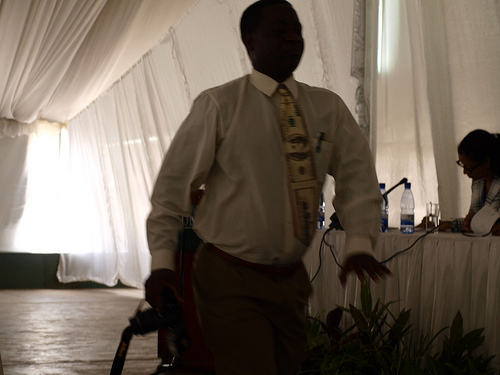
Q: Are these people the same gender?
A: No, they are both male and female.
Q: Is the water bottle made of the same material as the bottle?
A: Yes, both the water bottle and the bottle are made of plastic.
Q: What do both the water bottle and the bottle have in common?
A: The material, both the water bottle and the bottle are plastic.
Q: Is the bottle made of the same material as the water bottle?
A: Yes, both the bottle and the water bottle are made of plastic.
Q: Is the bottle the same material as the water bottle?
A: Yes, both the bottle and the water bottle are made of plastic.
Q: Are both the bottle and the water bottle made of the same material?
A: Yes, both the bottle and the water bottle are made of plastic.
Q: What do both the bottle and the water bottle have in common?
A: The material, both the bottle and the water bottle are plastic.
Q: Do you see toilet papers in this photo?
A: No, there are no toilet papers.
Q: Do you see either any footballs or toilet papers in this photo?
A: No, there are no toilet papers or footballs.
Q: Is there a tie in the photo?
A: Yes, there is a tie.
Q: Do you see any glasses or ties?
A: Yes, there is a tie.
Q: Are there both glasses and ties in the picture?
A: Yes, there are both a tie and glasses.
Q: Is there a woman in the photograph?
A: Yes, there is a woman.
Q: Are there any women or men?
A: Yes, there is a woman.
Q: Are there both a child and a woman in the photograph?
A: No, there is a woman but no children.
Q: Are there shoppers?
A: No, there are no shoppers.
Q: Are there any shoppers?
A: No, there are no shoppers.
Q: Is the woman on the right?
A: Yes, the woman is on the right of the image.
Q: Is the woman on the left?
A: No, the woman is on the right of the image.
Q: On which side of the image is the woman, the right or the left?
A: The woman is on the right of the image.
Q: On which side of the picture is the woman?
A: The woman is on the right of the image.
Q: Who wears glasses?
A: The woman wears glasses.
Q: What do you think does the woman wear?
A: The woman wears glasses.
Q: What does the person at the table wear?
A: The woman wears glasses.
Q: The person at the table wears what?
A: The woman wears glasses.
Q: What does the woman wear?
A: The woman wears glasses.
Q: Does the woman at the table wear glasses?
A: Yes, the woman wears glasses.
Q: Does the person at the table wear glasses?
A: Yes, the woman wears glasses.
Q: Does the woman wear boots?
A: No, the woman wears glasses.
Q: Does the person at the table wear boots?
A: No, the woman wears glasses.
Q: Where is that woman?
A: The woman is at the table.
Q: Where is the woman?
A: The woman is at the table.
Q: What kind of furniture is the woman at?
A: The woman is at the table.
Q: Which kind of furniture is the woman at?
A: The woman is at the table.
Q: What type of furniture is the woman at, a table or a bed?
A: The woman is at a table.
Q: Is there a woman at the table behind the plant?
A: Yes, there is a woman at the table.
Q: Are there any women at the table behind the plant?
A: Yes, there is a woman at the table.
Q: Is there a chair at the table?
A: No, there is a woman at the table.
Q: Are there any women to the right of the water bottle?
A: Yes, there is a woman to the right of the water bottle.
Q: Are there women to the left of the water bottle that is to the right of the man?
A: No, the woman is to the right of the water bottle.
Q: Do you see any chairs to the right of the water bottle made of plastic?
A: No, there is a woman to the right of the water bottle.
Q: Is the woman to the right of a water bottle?
A: Yes, the woman is to the right of a water bottle.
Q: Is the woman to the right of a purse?
A: No, the woman is to the right of a water bottle.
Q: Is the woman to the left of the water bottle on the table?
A: No, the woman is to the right of the water bottle.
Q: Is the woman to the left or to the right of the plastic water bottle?
A: The woman is to the right of the water bottle.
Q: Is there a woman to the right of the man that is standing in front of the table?
A: Yes, there is a woman to the right of the man.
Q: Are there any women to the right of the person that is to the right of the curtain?
A: Yes, there is a woman to the right of the man.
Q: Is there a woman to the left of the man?
A: No, the woman is to the right of the man.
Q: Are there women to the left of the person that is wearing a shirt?
A: No, the woman is to the right of the man.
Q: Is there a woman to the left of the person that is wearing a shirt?
A: No, the woman is to the right of the man.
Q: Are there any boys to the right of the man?
A: No, there is a woman to the right of the man.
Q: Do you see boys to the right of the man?
A: No, there is a woman to the right of the man.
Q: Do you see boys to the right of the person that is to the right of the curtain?
A: No, there is a woman to the right of the man.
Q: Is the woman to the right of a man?
A: Yes, the woman is to the right of a man.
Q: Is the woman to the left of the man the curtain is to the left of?
A: No, the woman is to the right of the man.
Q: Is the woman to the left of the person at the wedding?
A: No, the woman is to the right of the man.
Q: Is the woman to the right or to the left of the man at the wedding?
A: The woman is to the right of the man.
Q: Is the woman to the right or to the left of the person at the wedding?
A: The woman is to the right of the man.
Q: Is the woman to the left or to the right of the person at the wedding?
A: The woman is to the right of the man.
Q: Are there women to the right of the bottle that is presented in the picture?
A: Yes, there is a woman to the right of the bottle.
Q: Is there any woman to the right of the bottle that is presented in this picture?
A: Yes, there is a woman to the right of the bottle.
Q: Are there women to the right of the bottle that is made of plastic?
A: Yes, there is a woman to the right of the bottle.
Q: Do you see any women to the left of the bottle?
A: No, the woman is to the right of the bottle.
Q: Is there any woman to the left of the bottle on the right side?
A: No, the woman is to the right of the bottle.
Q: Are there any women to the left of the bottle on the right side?
A: No, the woman is to the right of the bottle.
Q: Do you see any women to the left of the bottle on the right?
A: No, the woman is to the right of the bottle.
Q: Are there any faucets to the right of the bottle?
A: No, there is a woman to the right of the bottle.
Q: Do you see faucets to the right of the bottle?
A: No, there is a woman to the right of the bottle.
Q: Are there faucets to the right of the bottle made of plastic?
A: No, there is a woman to the right of the bottle.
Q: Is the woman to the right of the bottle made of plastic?
A: Yes, the woman is to the right of the bottle.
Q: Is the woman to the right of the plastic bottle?
A: Yes, the woman is to the right of the bottle.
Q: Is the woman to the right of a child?
A: No, the woman is to the right of the bottle.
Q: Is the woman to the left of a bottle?
A: No, the woman is to the right of a bottle.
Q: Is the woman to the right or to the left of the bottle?
A: The woman is to the right of the bottle.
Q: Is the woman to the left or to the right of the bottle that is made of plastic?
A: The woman is to the right of the bottle.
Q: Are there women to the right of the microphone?
A: Yes, there is a woman to the right of the microphone.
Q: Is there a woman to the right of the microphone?
A: Yes, there is a woman to the right of the microphone.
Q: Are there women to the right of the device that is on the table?
A: Yes, there is a woman to the right of the microphone.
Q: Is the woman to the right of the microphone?
A: Yes, the woman is to the right of the microphone.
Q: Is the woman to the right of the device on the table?
A: Yes, the woman is to the right of the microphone.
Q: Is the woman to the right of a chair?
A: No, the woman is to the right of the microphone.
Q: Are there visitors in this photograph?
A: No, there are no visitors.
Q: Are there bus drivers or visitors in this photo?
A: No, there are no visitors or bus drivers.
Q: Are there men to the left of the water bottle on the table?
A: Yes, there is a man to the left of the water bottle.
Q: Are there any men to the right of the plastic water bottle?
A: No, the man is to the left of the water bottle.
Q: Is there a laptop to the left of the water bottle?
A: No, there is a man to the left of the water bottle.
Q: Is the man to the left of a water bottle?
A: Yes, the man is to the left of a water bottle.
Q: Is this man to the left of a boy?
A: No, the man is to the left of a water bottle.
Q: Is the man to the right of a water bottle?
A: No, the man is to the left of a water bottle.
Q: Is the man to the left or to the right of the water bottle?
A: The man is to the left of the water bottle.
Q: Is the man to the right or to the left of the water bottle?
A: The man is to the left of the water bottle.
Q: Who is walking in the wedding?
A: The man is walking in the wedding.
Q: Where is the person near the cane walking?
A: The man is walking in the wedding.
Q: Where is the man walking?
A: The man is walking in the wedding.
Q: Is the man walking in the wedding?
A: Yes, the man is walking in the wedding.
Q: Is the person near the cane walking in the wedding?
A: Yes, the man is walking in the wedding.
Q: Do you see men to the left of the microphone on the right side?
A: Yes, there is a man to the left of the microphone.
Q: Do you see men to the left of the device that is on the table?
A: Yes, there is a man to the left of the microphone.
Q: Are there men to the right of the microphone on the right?
A: No, the man is to the left of the microphone.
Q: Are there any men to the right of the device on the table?
A: No, the man is to the left of the microphone.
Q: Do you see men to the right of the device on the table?
A: No, the man is to the left of the microphone.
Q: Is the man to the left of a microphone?
A: Yes, the man is to the left of a microphone.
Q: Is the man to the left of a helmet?
A: No, the man is to the left of a microphone.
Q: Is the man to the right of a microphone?
A: No, the man is to the left of a microphone.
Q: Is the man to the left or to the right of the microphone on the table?
A: The man is to the left of the microphone.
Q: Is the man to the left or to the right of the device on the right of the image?
A: The man is to the left of the microphone.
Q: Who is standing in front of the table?
A: The man is standing in front of the table.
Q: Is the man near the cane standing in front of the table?
A: Yes, the man is standing in front of the table.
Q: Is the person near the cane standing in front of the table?
A: Yes, the man is standing in front of the table.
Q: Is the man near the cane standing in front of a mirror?
A: No, the man is standing in front of the table.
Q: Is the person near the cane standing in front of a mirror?
A: No, the man is standing in front of the table.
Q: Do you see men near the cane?
A: Yes, there is a man near the cane.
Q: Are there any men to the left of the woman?
A: Yes, there is a man to the left of the woman.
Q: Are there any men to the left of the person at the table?
A: Yes, there is a man to the left of the woman.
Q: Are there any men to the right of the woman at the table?
A: No, the man is to the left of the woman.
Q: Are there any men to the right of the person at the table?
A: No, the man is to the left of the woman.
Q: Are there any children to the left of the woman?
A: No, there is a man to the left of the woman.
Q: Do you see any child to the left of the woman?
A: No, there is a man to the left of the woman.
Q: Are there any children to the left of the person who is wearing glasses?
A: No, there is a man to the left of the woman.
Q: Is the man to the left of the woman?
A: Yes, the man is to the left of the woman.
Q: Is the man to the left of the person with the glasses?
A: Yes, the man is to the left of the woman.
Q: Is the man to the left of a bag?
A: No, the man is to the left of the woman.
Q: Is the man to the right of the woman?
A: No, the man is to the left of the woman.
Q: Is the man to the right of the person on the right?
A: No, the man is to the left of the woman.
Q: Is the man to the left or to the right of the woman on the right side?
A: The man is to the left of the woman.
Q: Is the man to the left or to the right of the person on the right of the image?
A: The man is to the left of the woman.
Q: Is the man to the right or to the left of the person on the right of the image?
A: The man is to the left of the woman.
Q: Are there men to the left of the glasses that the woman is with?
A: Yes, there is a man to the left of the glasses.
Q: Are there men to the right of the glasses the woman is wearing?
A: No, the man is to the left of the glasses.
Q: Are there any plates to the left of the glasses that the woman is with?
A: No, there is a man to the left of the glasses.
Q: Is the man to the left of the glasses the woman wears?
A: Yes, the man is to the left of the glasses.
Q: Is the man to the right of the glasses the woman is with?
A: No, the man is to the left of the glasses.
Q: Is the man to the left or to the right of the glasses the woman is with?
A: The man is to the left of the glasses.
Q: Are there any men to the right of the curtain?
A: Yes, there is a man to the right of the curtain.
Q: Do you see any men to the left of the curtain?
A: No, the man is to the right of the curtain.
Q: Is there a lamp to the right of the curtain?
A: No, there is a man to the right of the curtain.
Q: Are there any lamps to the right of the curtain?
A: No, there is a man to the right of the curtain.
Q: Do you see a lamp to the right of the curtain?
A: No, there is a man to the right of the curtain.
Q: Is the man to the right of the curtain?
A: Yes, the man is to the right of the curtain.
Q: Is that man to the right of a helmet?
A: No, the man is to the right of the curtain.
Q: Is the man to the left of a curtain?
A: No, the man is to the right of a curtain.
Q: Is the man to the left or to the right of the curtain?
A: The man is to the right of the curtain.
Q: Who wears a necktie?
A: The man wears a necktie.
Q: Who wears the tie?
A: The man wears a necktie.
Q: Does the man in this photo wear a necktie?
A: Yes, the man wears a necktie.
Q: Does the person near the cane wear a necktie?
A: Yes, the man wears a necktie.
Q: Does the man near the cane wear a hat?
A: No, the man wears a necktie.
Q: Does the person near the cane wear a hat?
A: No, the man wears a necktie.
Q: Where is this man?
A: The man is at the wedding.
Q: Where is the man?
A: The man is at the wedding.